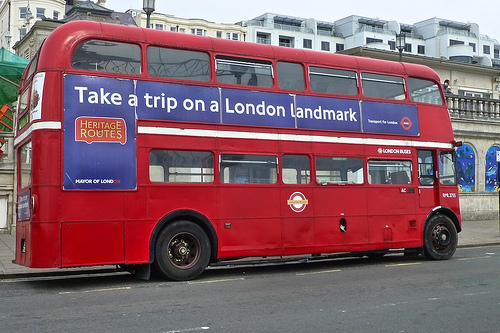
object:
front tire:
[421, 214, 459, 261]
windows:
[71, 36, 141, 77]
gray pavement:
[321, 268, 446, 321]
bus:
[9, 21, 463, 282]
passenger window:
[147, 147, 213, 183]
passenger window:
[316, 156, 364, 184]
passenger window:
[309, 63, 356, 95]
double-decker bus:
[10, 19, 462, 282]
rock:
[301, 61, 361, 96]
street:
[0, 239, 498, 331]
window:
[218, 153, 277, 184]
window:
[278, 151, 313, 183]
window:
[370, 161, 410, 188]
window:
[405, 71, 445, 103]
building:
[415, 16, 497, 66]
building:
[334, 13, 424, 54]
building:
[249, 12, 343, 54]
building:
[176, 18, 252, 42]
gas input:
[339, 217, 348, 233]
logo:
[74, 115, 127, 145]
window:
[307, 64, 361, 98]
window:
[359, 72, 406, 100]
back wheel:
[154, 219, 213, 282]